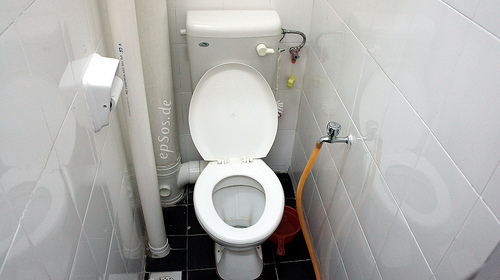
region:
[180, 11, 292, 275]
A WHITE TOILET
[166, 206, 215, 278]
BLACK FLOOR TILES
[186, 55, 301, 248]
A WHITE PLASTIC TOILET SEAT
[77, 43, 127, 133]
TOILET PAPER HOLDER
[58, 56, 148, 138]
TOILET PAPER IN A HOLDER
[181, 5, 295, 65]
A WHITE TOILET TANK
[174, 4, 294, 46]
WHITE TANK COVER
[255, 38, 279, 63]
A FLUSHER HANDLE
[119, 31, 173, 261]
A WHITE PIPE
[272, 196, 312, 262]
A RED PLASTIC PAN ON THE FLOOR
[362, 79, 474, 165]
the walls are tiled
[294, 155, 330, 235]
the hose is orange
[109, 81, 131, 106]
the tissue is white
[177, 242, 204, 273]
the tiles are black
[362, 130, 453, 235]
toilet refection on the wall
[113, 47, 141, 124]
blue writing on the pipe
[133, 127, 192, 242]
pipe made of plastic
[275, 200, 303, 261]
the utensil is red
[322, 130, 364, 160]
the tap is mettalic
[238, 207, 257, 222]
stains in the toilet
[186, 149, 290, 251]
Toilet bowl White toilet stains in toilet Toilet seat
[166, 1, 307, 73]
Toilet tank White toilet Toilet flusher Silver water pipe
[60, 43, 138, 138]
Toilet paper dispenser toilet paper roll White dispenser white toilet paper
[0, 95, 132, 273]
White bathroom tile Reflection of toilet toilet paper dispenser Clean tile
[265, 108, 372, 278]
Silver faucet yellow hose White bathroom tile red handled cup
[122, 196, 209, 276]
Black tile White pipe White grout on tile part of drain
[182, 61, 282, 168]
Toilet lid white toilet lid Toilet lid up Toilet tank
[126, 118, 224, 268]
White pipes two pipes black tile White grout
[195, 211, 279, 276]
White toilet Toilet base two screws black tile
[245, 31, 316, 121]
Toilet brush Toilet flusher white toilet white tile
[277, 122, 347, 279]
This is an orange pipe.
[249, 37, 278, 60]
This is a toilet flusher.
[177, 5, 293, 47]
This is a tank lid.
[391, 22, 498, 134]
These are white tiles.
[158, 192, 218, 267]
These are black tiles.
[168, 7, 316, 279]
This is a toilet.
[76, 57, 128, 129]
This is a toilet paper holder.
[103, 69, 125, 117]
This is toilet paper.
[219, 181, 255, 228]
This is a toilet bowl.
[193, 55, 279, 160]
This is a toilet lid.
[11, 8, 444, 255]
This is a bathroom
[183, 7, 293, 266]
The toilet is white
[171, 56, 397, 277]
The floor and walls are tile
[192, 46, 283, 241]
The lid is up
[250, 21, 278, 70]
This flushes the toilet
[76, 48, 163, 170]
This holds toilet paper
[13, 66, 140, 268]
There is a reflection on the wall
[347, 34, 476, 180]
The tiles are square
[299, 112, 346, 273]
The hose is orange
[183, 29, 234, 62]
The toilet is labelled